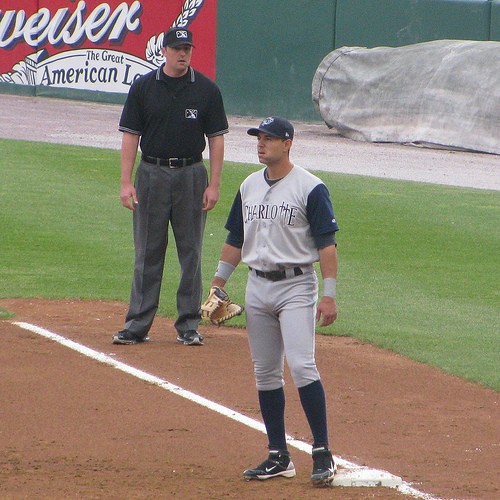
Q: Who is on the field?
A: A baseball player.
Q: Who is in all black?
A: The unpire.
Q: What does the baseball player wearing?
A: White and blue uniform.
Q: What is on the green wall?
A: An advertisement.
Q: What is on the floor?
A: A white tarp.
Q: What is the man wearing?
A: Gray pants.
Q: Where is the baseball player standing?
A: At the plate.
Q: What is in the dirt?
A: White line.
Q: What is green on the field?
A: Grass.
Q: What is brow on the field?
A: Dirt.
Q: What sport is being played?
A: Baseball.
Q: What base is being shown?
A: First.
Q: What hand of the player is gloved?
A: Right.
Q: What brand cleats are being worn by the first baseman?
A: Nike.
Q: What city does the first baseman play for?
A: Charlotte.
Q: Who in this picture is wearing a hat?
A: Both men.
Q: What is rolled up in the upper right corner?
A: A tarp.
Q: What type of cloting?
A: Uniform.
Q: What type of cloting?
A: Uniform.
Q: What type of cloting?
A: Uniform.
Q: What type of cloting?
A: Uniform.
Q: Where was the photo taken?
A: At a baseball game.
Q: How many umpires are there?
A: One.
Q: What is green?
A: Grass.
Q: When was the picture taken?
A: Daytime.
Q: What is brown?
A: Dirt.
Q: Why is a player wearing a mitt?
A: To play baseball.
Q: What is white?
A: Line on dirt.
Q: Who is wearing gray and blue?
A: Baseball player.